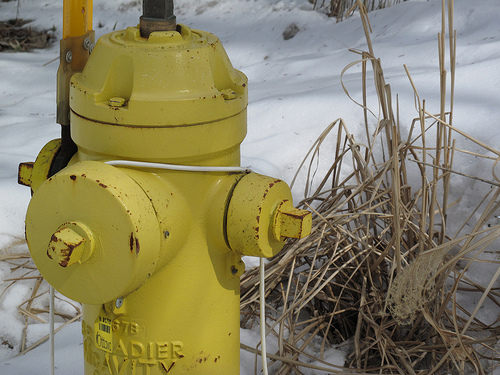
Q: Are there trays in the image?
A: No, there are no trays.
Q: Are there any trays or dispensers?
A: No, there are no trays or dispensers.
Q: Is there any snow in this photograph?
A: Yes, there is snow.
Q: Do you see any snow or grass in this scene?
A: Yes, there is snow.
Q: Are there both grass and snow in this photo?
A: Yes, there are both snow and grass.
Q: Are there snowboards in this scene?
A: No, there are no snowboards.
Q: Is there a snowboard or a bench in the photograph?
A: No, there are no snowboards or benches.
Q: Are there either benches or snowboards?
A: No, there are no snowboards or benches.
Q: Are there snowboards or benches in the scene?
A: No, there are no snowboards or benches.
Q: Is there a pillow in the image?
A: No, there are no pillows.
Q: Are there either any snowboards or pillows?
A: No, there are no pillows or snowboards.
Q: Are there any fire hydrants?
A: Yes, there is a fire hydrant.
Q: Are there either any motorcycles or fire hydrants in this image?
A: Yes, there is a fire hydrant.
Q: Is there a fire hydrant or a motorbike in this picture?
A: Yes, there is a fire hydrant.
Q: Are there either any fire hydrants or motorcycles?
A: Yes, there is a fire hydrant.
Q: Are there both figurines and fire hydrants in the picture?
A: No, there is a fire hydrant but no figurines.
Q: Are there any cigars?
A: No, there are no cigars.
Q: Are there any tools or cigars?
A: No, there are no cigars or tools.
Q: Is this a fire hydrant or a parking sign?
A: This is a fire hydrant.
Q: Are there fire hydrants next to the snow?
A: Yes, there is a fire hydrant next to the snow.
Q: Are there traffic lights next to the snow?
A: No, there is a fire hydrant next to the snow.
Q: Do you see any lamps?
A: No, there are no lamps.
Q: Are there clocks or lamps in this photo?
A: No, there are no lamps or clocks.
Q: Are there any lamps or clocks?
A: No, there are no lamps or clocks.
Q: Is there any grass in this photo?
A: Yes, there is grass.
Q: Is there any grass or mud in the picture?
A: Yes, there is grass.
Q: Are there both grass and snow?
A: Yes, there are both grass and snow.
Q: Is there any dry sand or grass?
A: Yes, there is dry grass.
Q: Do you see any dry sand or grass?
A: Yes, there is dry grass.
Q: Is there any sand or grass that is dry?
A: Yes, the grass is dry.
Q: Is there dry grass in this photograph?
A: Yes, there is dry grass.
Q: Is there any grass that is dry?
A: Yes, there is grass that is dry.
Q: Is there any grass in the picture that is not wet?
A: Yes, there is dry grass.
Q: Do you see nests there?
A: No, there are no nests.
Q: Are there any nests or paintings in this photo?
A: No, there are no nests or paintings.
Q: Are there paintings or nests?
A: No, there are no nests or paintings.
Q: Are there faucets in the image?
A: No, there are no faucets.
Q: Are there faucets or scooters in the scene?
A: No, there are no faucets or scooters.